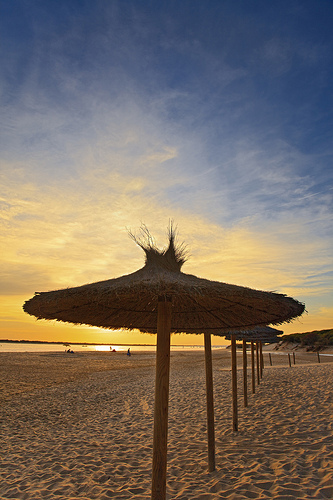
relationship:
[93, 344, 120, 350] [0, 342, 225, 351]
reflection on water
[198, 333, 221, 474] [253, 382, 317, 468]
pole in sand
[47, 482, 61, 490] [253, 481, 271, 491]
footprint on footprint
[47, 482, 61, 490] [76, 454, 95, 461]
footprint on footprint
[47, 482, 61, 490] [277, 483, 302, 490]
footprint on footprint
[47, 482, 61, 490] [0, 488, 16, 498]
footprint on footprint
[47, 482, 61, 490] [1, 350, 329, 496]
footprint on sand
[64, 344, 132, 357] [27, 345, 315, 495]
people on sandy beach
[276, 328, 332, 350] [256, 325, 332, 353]
grass on bluff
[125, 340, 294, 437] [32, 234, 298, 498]
poles holding up huts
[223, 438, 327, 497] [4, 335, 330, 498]
foot prints in sand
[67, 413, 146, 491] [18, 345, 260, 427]
part of shore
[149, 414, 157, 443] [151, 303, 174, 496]
edge of a poles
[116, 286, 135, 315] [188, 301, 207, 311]
part of a roof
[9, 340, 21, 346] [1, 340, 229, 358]
part of an ocean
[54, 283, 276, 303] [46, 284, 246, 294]
edge of a roof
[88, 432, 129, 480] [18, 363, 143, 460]
part of beach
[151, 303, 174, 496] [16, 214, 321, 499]
poles closest to umbrella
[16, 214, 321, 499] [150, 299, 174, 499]
umbrella in a pole